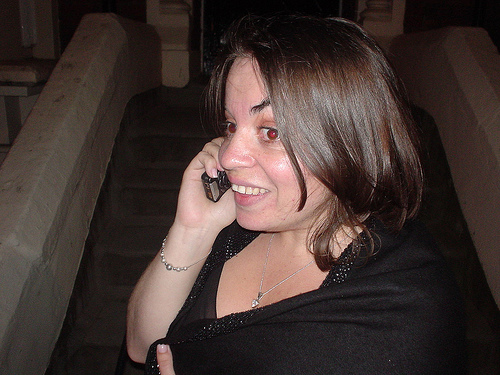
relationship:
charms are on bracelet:
[160, 242, 187, 275] [155, 237, 216, 276]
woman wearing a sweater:
[126, 15, 464, 375] [115, 219, 462, 375]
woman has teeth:
[126, 15, 464, 375] [226, 184, 269, 197]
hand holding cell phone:
[174, 137, 240, 240] [196, 159, 237, 205]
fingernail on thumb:
[156, 344, 169, 353] [155, 343, 176, 374]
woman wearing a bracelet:
[126, 15, 464, 375] [155, 237, 216, 276]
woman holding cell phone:
[126, 15, 464, 375] [196, 159, 237, 205]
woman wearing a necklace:
[126, 15, 464, 375] [243, 231, 335, 310]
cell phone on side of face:
[196, 159, 237, 205] [212, 57, 324, 239]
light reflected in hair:
[272, 71, 419, 187] [205, 13, 424, 272]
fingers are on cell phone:
[200, 138, 229, 181] [196, 159, 237, 205]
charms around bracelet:
[160, 242, 187, 275] [155, 237, 216, 276]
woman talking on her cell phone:
[126, 15, 464, 375] [196, 159, 237, 205]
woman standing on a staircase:
[126, 15, 464, 375] [4, 13, 498, 373]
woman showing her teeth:
[126, 15, 464, 375] [226, 184, 269, 197]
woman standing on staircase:
[126, 15, 464, 375] [4, 13, 498, 373]